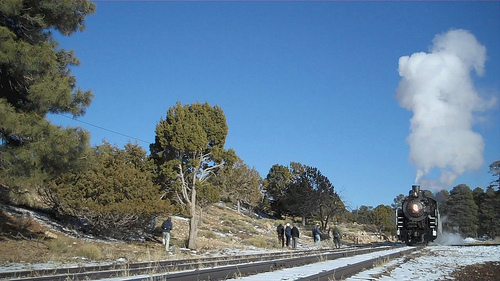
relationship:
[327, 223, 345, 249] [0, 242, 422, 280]
people near tracks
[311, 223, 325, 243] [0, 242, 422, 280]
people near tracks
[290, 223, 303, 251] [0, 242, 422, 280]
people near tracks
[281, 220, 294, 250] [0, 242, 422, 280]
people near tracks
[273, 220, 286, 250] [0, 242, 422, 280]
people near tracks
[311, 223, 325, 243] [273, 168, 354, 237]
people near tree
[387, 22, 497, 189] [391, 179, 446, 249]
smoke from train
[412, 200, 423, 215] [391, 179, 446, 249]
spot front train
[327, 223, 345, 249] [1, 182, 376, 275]
people on grass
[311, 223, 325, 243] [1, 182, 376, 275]
people on grass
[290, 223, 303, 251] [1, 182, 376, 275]
people on grass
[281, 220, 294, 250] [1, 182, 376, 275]
people on grass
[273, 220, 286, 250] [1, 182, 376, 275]
people on grass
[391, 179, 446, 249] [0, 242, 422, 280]
train on tracks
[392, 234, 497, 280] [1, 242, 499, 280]
snow on ground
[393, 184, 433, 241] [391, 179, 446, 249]
front of train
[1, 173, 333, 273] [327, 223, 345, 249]
hill by people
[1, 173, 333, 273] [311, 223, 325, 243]
hill by people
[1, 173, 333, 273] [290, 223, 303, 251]
hill by people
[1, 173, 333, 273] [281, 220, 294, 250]
hill by people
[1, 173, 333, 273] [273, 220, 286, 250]
hill by people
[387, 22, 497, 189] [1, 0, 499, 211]
smoke against sky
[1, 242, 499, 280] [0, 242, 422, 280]
ground near tracks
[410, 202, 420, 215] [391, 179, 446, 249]
headlight on train